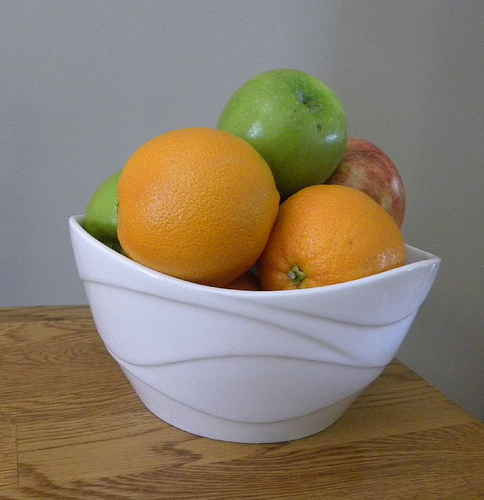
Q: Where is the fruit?
A: In the white bowl.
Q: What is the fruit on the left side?
A: An orange.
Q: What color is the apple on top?
A: Green.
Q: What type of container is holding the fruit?
A: A white bowl.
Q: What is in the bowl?
A: Fruit.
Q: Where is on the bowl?
A: A table.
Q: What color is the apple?
A: Green.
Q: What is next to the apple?
A: Oranges.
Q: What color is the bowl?
A: White.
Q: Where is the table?
A: By the wall.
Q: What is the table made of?
A: Wood.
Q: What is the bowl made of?
A: Glass.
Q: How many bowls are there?
A: One.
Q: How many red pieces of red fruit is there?
A: One.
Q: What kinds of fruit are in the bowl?
A: Orange and apples.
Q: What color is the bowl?
A: White.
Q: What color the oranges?
A: Orange.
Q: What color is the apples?
A: Green.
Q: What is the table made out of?
A: Wood.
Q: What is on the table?
A: A bowl of fruit.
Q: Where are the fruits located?
A: On a table.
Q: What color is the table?
A: Tan, brownish.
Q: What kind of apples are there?
A: Granny smith.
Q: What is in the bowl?
A: Apples and oranges.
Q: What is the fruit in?
A: A bowl.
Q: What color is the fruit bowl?
A: White.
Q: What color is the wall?
A: Grey.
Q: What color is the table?
A: Brown.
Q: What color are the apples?
A: Green and red.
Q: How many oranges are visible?
A: Two.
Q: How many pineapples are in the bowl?
A: Zero.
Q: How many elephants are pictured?
A: Zero.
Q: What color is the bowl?
A: White.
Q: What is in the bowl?
A: Fruit.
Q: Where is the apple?
A: Behind the oranges.